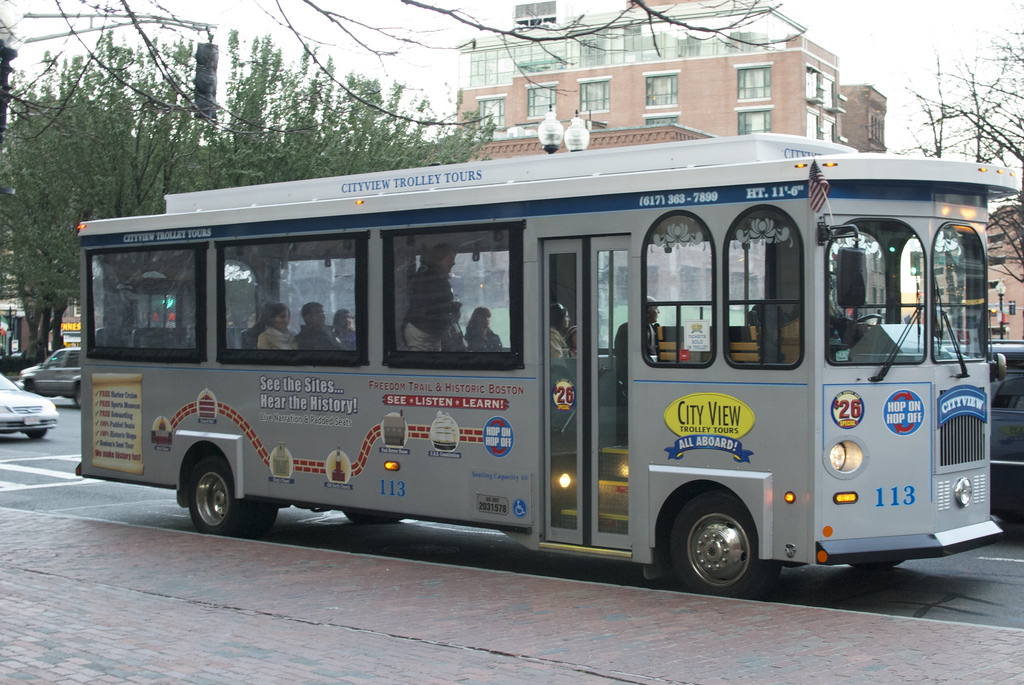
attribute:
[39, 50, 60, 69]
leaves — green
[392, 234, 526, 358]
glass — clear, clean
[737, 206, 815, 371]
glass — clean, clear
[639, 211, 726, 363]
glass — clear, clean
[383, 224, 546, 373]
glass — clean, clear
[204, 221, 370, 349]
glass — clear, clean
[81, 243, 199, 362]
glass — clean, clear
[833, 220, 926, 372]
glass — clear, clean